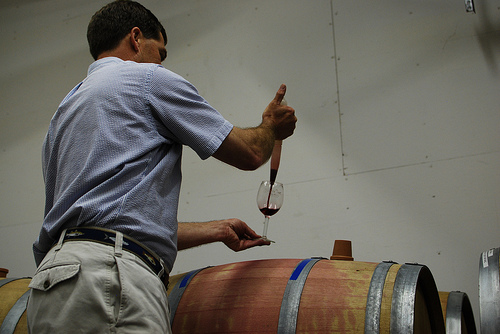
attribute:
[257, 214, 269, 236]
stem — thick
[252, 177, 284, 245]
wine glass — transparent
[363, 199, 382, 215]
ground — black, short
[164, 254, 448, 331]
barrel — light brown, brown, wooden, stained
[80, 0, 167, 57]
hair — short, brown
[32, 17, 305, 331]
man — working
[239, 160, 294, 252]
wine — red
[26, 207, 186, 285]
belt — patterned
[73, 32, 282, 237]
man — tall, fit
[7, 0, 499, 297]
walls — plain, white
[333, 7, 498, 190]
wall — white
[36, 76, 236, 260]
shirt — collared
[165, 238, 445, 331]
barrel — wooden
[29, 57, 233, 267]
shirt — blue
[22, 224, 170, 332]
pants — khaki